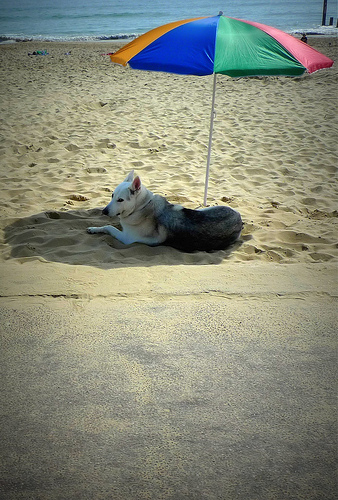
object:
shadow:
[0, 203, 248, 272]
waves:
[0, 21, 338, 43]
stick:
[329, 16, 333, 25]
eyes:
[111, 193, 124, 204]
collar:
[135, 193, 154, 211]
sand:
[0, 293, 338, 500]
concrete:
[0, 296, 338, 500]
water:
[0, 1, 338, 39]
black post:
[321, 0, 328, 27]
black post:
[329, 16, 334, 24]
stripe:
[212, 13, 307, 77]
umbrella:
[107, 9, 334, 207]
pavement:
[0, 296, 338, 500]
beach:
[0, 30, 338, 500]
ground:
[0, 42, 338, 500]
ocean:
[0, 0, 338, 44]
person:
[300, 32, 307, 44]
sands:
[0, 35, 338, 299]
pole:
[203, 73, 218, 206]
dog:
[86, 170, 244, 254]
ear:
[128, 175, 142, 192]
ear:
[123, 169, 135, 183]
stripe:
[126, 18, 215, 82]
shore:
[0, 27, 336, 52]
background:
[0, 0, 337, 104]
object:
[28, 49, 50, 57]